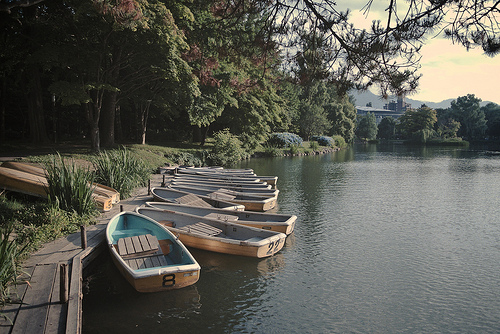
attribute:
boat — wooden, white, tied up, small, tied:
[107, 206, 202, 293]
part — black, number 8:
[162, 271, 180, 288]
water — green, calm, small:
[82, 150, 499, 333]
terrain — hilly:
[0, 125, 232, 286]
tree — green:
[1, 4, 194, 153]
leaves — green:
[105, 5, 184, 84]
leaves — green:
[75, 3, 123, 84]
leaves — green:
[29, 2, 80, 77]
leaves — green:
[1, 8, 38, 90]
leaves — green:
[117, 9, 198, 107]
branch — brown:
[110, 34, 125, 82]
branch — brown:
[73, 45, 94, 88]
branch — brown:
[120, 60, 149, 86]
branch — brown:
[14, 36, 51, 94]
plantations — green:
[1, 214, 30, 293]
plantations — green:
[41, 149, 92, 230]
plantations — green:
[16, 198, 66, 250]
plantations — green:
[85, 155, 129, 198]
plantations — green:
[111, 149, 150, 185]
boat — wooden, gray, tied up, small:
[133, 206, 286, 258]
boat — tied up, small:
[153, 185, 244, 213]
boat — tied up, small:
[173, 183, 279, 212]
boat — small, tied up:
[169, 175, 272, 190]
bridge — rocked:
[250, 145, 341, 156]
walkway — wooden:
[2, 159, 122, 211]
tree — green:
[120, 21, 203, 146]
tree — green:
[181, 11, 277, 147]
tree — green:
[289, 42, 329, 140]